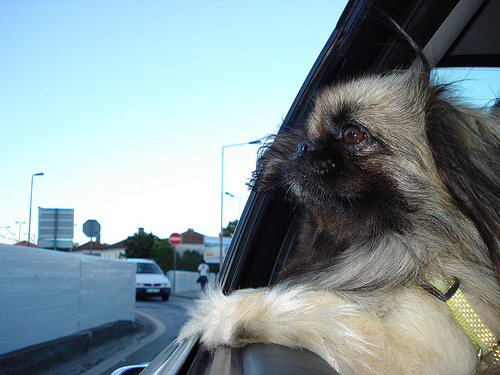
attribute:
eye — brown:
[323, 115, 363, 157]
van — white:
[118, 252, 172, 305]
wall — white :
[0, 243, 138, 356]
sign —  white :
[167, 227, 186, 247]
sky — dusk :
[0, 0, 348, 250]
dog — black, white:
[169, 51, 499, 373]